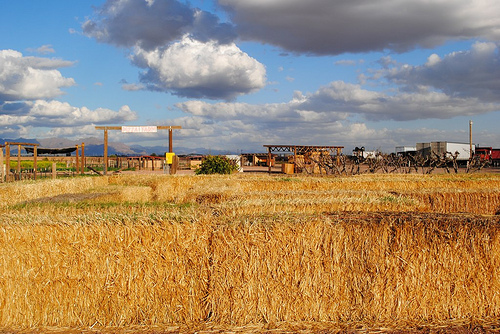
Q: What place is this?
A: It is a field.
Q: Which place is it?
A: It is a field.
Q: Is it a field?
A: Yes, it is a field.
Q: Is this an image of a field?
A: Yes, it is showing a field.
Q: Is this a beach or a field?
A: It is a field.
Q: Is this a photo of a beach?
A: No, the picture is showing a field.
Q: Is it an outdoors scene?
A: Yes, it is outdoors.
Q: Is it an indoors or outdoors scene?
A: It is outdoors.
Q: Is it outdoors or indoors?
A: It is outdoors.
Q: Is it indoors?
A: No, it is outdoors.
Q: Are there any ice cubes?
A: No, there are no ice cubes.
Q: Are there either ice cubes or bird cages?
A: No, there are no ice cubes or bird cages.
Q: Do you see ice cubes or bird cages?
A: No, there are no ice cubes or bird cages.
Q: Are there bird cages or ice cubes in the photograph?
A: No, there are no ice cubes or bird cages.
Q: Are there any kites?
A: No, there are no kites.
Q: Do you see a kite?
A: No, there are no kites.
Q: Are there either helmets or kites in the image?
A: No, there are no kites or helmets.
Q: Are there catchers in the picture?
A: No, there are no catchers.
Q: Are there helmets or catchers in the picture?
A: No, there are no catchers or helmets.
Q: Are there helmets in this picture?
A: No, there are no helmets.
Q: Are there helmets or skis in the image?
A: No, there are no helmets or skis.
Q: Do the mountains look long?
A: Yes, the mountains are long.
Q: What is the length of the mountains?
A: The mountains are long.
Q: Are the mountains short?
A: No, the mountains are long.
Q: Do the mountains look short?
A: No, the mountains are long.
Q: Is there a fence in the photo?
A: Yes, there is a fence.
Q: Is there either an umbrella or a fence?
A: Yes, there is a fence.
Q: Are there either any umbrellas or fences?
A: Yes, there is a fence.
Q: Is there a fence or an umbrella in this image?
A: Yes, there is a fence.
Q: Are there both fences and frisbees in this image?
A: No, there is a fence but no frisbees.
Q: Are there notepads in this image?
A: No, there are no notepads.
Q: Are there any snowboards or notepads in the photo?
A: No, there are no notepads or snowboards.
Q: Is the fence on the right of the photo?
A: Yes, the fence is on the right of the image.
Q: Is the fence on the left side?
A: No, the fence is on the right of the image.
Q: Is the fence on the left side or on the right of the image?
A: The fence is on the right of the image.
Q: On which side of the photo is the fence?
A: The fence is on the right of the image.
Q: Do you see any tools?
A: No, there are no tools.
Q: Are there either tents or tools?
A: No, there are no tools or tents.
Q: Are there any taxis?
A: Yes, there is a taxi.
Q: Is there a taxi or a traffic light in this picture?
A: Yes, there is a taxi.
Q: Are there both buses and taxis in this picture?
A: No, there is a taxi but no buses.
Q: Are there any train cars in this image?
A: No, there are no train cars.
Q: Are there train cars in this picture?
A: No, there are no train cars.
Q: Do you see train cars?
A: No, there are no train cars.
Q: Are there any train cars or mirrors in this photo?
A: No, there are no train cars or mirrors.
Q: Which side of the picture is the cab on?
A: The cab is on the right of the image.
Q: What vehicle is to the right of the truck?
A: The vehicle is a taxi.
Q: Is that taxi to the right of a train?
A: No, the taxi is to the right of the truck.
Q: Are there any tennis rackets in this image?
A: No, there are no tennis rackets.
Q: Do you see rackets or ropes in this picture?
A: No, there are no rackets or ropes.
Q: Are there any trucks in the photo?
A: Yes, there is a truck.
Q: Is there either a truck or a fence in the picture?
A: Yes, there is a truck.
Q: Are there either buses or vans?
A: No, there are no buses or vans.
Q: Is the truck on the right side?
A: Yes, the truck is on the right of the image.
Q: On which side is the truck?
A: The truck is on the right of the image.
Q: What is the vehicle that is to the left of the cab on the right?
A: The vehicle is a truck.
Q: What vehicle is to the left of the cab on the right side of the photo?
A: The vehicle is a truck.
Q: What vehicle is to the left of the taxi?
A: The vehicle is a truck.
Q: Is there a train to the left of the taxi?
A: No, there is a truck to the left of the taxi.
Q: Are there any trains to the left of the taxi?
A: No, there is a truck to the left of the taxi.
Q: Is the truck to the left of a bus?
A: No, the truck is to the left of the taxi.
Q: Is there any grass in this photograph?
A: Yes, there is grass.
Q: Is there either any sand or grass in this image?
A: Yes, there is grass.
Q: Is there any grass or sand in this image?
A: Yes, there is grass.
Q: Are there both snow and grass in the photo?
A: No, there is grass but no snow.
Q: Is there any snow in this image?
A: No, there is no snow.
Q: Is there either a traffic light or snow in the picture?
A: No, there are no snow or traffic lights.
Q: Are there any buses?
A: No, there are no buses.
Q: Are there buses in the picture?
A: No, there are no buses.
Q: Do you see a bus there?
A: No, there are no buses.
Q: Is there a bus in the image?
A: No, there are no buses.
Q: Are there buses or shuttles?
A: No, there are no buses or shuttles.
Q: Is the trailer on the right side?
A: Yes, the trailer is on the right of the image.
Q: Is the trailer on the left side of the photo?
A: No, the trailer is on the right of the image.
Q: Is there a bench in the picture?
A: No, there are no benches.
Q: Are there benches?
A: No, there are no benches.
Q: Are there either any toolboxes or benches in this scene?
A: No, there are no benches or toolboxes.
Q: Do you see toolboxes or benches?
A: No, there are no benches or toolboxes.